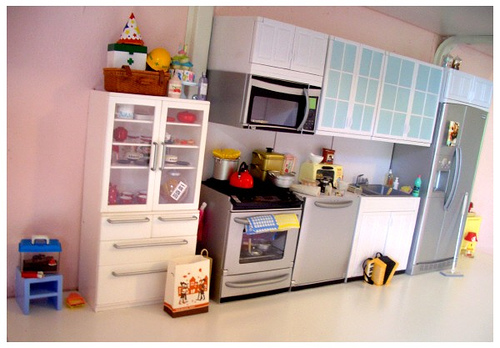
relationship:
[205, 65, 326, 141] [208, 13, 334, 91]
microwave under cabinet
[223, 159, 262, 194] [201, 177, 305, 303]
tea kettle on oven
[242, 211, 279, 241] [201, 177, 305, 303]
towel on oven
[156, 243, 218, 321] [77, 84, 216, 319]
bag in front of cabinet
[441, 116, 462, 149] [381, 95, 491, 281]
picture on refrigerator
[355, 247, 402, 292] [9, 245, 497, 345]
case on floor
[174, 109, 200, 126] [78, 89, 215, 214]
bowl in cabinet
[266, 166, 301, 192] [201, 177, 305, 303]
pot on oven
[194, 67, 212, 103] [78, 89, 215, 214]
bottle on cabinet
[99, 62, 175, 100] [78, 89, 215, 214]
basket on top of cabinet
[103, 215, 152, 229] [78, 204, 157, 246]
handle on drawer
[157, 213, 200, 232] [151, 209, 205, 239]
handle on drawer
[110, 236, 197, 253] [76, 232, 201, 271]
handle on drawer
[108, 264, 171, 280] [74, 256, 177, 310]
handle on drawer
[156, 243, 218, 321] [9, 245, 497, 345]
bag on floor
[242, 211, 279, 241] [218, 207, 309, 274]
towel on oven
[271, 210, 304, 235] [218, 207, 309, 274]
towel on oven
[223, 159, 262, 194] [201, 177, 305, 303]
tea kettle on top of oven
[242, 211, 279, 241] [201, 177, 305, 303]
towel hanging on oven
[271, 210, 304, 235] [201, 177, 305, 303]
towel hanging on oven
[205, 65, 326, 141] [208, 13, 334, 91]
microwave beneath cabinet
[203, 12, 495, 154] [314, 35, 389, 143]
cabinets have door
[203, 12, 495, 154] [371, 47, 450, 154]
cabinets have door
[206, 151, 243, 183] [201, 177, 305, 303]
pot on oven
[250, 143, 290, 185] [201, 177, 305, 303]
pot on oven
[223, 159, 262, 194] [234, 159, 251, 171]
tea kettle has handle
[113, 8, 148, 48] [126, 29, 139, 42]
party hat has stars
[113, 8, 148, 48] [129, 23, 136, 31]
party hat has dots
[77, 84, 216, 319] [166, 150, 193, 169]
cabinet has dishes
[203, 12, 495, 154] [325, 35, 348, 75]
cabinets have square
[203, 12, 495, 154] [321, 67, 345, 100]
cabinets have square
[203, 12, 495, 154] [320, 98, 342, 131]
cabinets have square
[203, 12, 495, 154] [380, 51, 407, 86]
cabinets have square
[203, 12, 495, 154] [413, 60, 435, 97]
cabinets have square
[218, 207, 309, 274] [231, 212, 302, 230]
oven has handle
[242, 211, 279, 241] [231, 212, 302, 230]
towel on handle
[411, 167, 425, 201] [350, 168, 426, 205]
bottle on edge of sink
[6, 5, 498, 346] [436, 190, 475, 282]
kitchen has mop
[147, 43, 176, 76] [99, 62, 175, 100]
hard hat in basket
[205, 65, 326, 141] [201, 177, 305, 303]
microwave above oven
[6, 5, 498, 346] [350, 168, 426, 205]
kitchen has sink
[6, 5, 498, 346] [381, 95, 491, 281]
kitchen has refrigerator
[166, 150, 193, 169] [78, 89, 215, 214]
dishes are in cabinet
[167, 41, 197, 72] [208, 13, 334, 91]
toy next to cabinet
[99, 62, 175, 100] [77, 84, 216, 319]
basket on top of cabinet